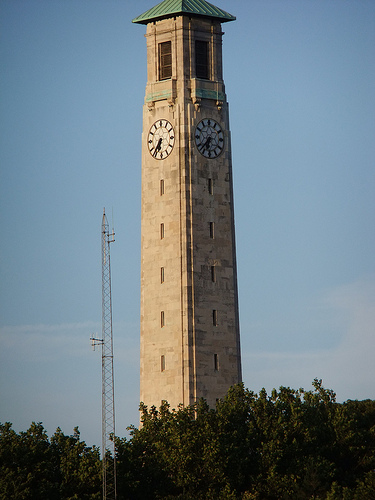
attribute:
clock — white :
[193, 116, 226, 158]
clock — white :
[141, 116, 178, 160]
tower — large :
[130, 2, 236, 393]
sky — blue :
[259, 65, 341, 175]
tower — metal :
[91, 204, 121, 494]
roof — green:
[130, 1, 236, 24]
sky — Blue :
[0, 1, 372, 459]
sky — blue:
[264, 121, 340, 206]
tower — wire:
[89, 201, 130, 449]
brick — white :
[191, 197, 207, 207]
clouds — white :
[7, 327, 78, 350]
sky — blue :
[259, 117, 370, 264]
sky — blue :
[235, 1, 373, 410]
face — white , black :
[195, 117, 227, 160]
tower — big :
[4, 3, 370, 486]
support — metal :
[89, 336, 102, 349]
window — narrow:
[155, 37, 176, 80]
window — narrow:
[192, 34, 208, 83]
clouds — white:
[253, 262, 373, 387]